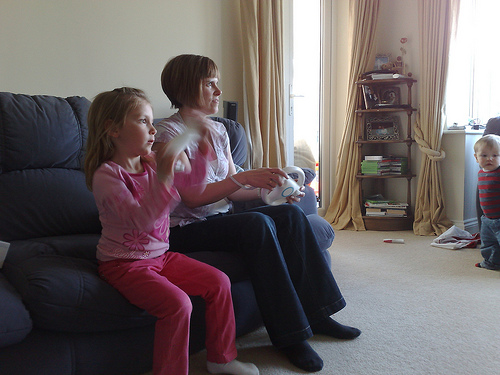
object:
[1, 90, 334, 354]
couch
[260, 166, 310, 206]
game controller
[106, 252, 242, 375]
pants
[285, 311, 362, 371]
socks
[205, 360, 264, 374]
sock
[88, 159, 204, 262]
top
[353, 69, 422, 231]
shelf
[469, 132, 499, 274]
boy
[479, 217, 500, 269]
jeans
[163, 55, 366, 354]
woman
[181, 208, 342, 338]
blue jeans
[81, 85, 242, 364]
girl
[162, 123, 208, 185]
game controller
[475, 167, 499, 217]
shirt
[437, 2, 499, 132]
window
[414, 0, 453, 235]
curtains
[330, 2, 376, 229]
curtains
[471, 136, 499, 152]
blond hair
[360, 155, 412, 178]
books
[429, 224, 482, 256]
plastic bag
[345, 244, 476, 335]
carpet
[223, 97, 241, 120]
speaker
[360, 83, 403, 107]
framed pictures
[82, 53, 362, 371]
two people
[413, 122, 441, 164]
rope